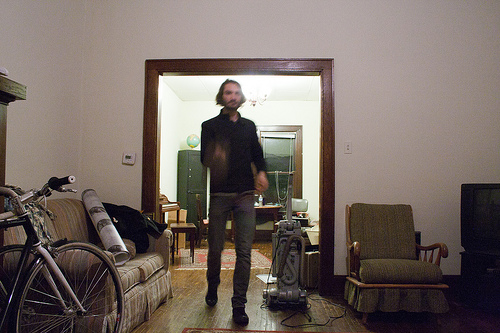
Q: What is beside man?
A: Vacuum.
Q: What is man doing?
A: Walking.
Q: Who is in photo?
A: Man.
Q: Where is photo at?
A: Living room.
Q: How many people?
A: One.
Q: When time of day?
A: Night.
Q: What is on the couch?
A: Paper.